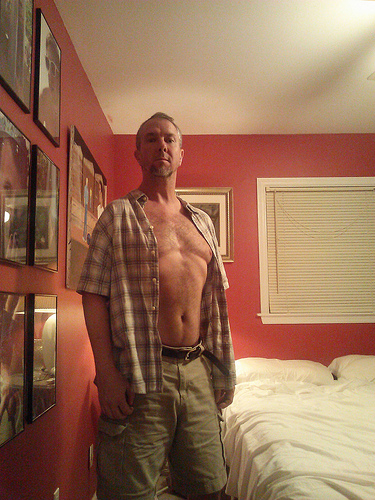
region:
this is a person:
[81, 111, 242, 491]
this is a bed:
[225, 348, 374, 498]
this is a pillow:
[237, 357, 333, 389]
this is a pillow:
[330, 349, 374, 382]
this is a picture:
[32, 7, 62, 143]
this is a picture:
[27, 289, 57, 420]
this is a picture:
[31, 144, 56, 270]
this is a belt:
[159, 343, 227, 375]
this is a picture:
[66, 119, 115, 295]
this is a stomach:
[159, 257, 202, 346]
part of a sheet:
[301, 439, 318, 469]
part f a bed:
[281, 439, 298, 477]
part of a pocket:
[210, 422, 227, 460]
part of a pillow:
[272, 359, 285, 386]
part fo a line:
[203, 434, 216, 464]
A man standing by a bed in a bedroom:
[76, 112, 236, 498]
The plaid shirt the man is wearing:
[76, 188, 235, 393]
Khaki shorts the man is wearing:
[96, 341, 227, 498]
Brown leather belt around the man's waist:
[161, 347, 228, 374]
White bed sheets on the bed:
[220, 358, 374, 498]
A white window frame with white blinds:
[256, 177, 374, 323]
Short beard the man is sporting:
[149, 162, 173, 179]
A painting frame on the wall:
[175, 186, 233, 262]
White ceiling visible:
[55, 0, 372, 133]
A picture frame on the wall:
[66, 126, 107, 288]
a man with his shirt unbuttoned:
[117, 202, 221, 368]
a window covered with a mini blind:
[248, 165, 354, 332]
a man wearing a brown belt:
[161, 341, 222, 364]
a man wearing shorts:
[122, 323, 223, 499]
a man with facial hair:
[130, 107, 186, 188]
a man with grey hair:
[126, 110, 191, 151]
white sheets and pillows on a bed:
[235, 348, 365, 497]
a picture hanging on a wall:
[15, 286, 63, 432]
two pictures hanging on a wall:
[0, 143, 65, 281]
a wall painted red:
[204, 132, 286, 173]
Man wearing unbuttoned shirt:
[76, 191, 237, 410]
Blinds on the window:
[269, 189, 371, 314]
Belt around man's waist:
[158, 339, 206, 363]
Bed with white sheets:
[222, 351, 373, 498]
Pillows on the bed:
[232, 354, 373, 386]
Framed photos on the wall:
[1, 0, 62, 445]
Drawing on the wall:
[65, 121, 112, 296]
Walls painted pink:
[1, 0, 373, 499]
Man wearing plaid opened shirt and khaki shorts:
[77, 111, 237, 498]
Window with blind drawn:
[254, 174, 372, 329]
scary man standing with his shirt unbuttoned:
[75, 111, 237, 498]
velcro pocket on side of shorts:
[93, 412, 126, 485]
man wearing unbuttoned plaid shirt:
[75, 111, 236, 498]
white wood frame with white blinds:
[252, 176, 373, 322]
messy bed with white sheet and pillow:
[218, 352, 373, 499]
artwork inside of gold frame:
[173, 185, 235, 265]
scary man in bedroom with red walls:
[1, 0, 372, 498]